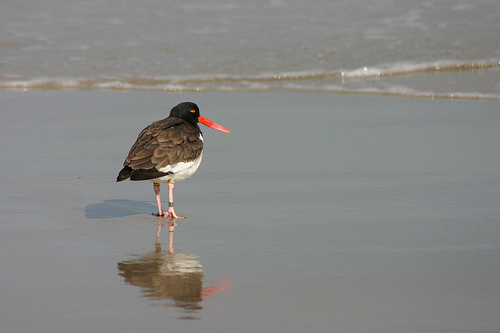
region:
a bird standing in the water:
[8, 16, 317, 329]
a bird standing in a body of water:
[91, 83, 297, 315]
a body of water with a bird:
[33, 66, 395, 329]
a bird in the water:
[72, 77, 318, 318]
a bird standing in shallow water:
[92, 43, 327, 330]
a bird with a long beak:
[100, 71, 240, 183]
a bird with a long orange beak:
[82, 59, 248, 226]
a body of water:
[74, 28, 372, 299]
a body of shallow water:
[47, 73, 460, 330]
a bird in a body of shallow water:
[37, 80, 355, 330]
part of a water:
[257, 155, 304, 205]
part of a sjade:
[188, 283, 210, 313]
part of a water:
[316, 248, 352, 298]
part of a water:
[307, 238, 341, 282]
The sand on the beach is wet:
[235, 184, 477, 311]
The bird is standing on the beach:
[111, 94, 234, 230]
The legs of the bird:
[143, 188, 187, 226]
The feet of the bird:
[151, 205, 188, 222]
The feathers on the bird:
[124, 118, 201, 168]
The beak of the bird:
[198, 110, 231, 140]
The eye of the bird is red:
[183, 103, 200, 117]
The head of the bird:
[166, 96, 205, 126]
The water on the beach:
[137, 22, 448, 109]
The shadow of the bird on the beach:
[111, 216, 253, 321]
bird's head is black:
[159, 93, 234, 161]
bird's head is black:
[89, 65, 224, 228]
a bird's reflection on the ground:
[91, 209, 275, 331]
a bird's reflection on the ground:
[88, 68, 233, 330]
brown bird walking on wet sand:
[81, 92, 242, 221]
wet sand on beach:
[13, 22, 77, 106]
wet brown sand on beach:
[14, 59, 89, 184]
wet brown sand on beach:
[31, 133, 88, 221]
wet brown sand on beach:
[45, 215, 95, 283]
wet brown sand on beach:
[176, 239, 288, 319]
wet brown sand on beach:
[285, 201, 355, 285]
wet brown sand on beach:
[354, 184, 407, 251]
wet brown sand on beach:
[248, 109, 314, 190]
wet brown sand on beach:
[315, 56, 398, 136]